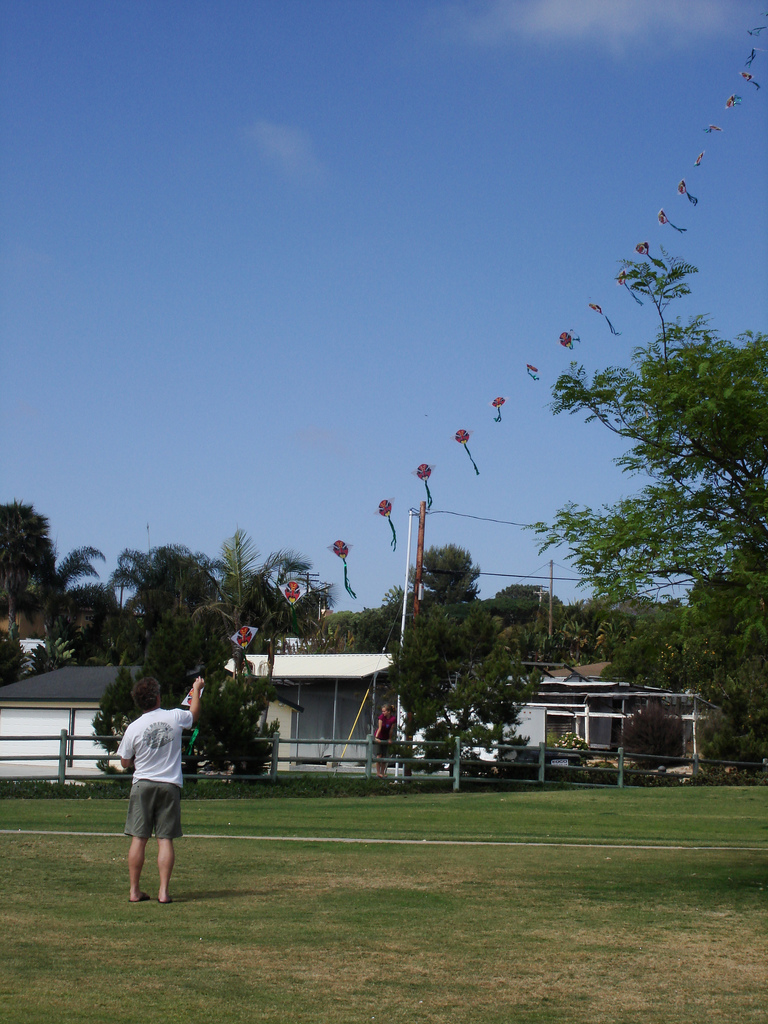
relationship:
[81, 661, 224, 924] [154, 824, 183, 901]
person has leg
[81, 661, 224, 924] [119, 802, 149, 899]
person has leg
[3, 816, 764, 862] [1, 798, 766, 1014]
line on ground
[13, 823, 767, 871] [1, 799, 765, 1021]
line on ground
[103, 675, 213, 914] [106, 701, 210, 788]
man wears shirt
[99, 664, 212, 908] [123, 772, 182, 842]
man wears pants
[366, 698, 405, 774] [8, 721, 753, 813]
girl leans on fence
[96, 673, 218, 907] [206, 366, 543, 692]
man holding kite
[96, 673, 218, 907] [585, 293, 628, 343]
man holding kite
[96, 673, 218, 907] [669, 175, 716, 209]
man holding kite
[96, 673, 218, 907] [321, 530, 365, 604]
man holding kite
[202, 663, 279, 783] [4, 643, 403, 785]
tree in front of house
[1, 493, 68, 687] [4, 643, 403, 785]
tree in front of house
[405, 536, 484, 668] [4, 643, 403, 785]
tree in front of house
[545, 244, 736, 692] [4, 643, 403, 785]
tree in front of house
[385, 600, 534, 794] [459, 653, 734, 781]
tree in front of house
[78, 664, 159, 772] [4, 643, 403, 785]
tree in front of house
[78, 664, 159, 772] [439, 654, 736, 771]
tree in front of house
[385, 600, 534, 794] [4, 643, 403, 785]
tree in front of house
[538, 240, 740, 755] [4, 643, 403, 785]
tree in front of house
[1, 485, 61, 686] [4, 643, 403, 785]
tree in front of house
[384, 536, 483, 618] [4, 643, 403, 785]
tree in front of house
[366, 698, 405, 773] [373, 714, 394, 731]
girl wearing shirt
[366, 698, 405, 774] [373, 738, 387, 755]
girl wearing shorts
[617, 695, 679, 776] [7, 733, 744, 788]
bush on fence